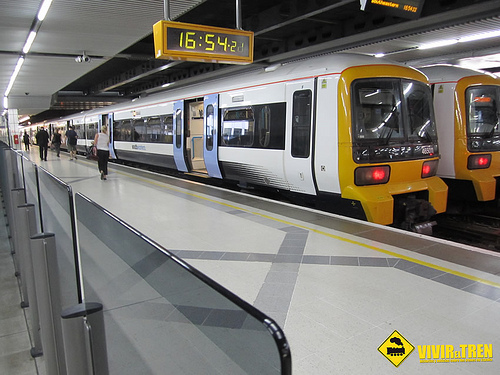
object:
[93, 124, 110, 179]
woman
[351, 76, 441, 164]
window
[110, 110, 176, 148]
window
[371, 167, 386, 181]
red ligth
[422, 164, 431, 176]
red ligth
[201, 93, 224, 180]
door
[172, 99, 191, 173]
door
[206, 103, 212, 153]
window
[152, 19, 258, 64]
sign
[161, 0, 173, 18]
pole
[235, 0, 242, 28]
pole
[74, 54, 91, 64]
camera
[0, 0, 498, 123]
ceiling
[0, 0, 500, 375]
train station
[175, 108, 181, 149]
window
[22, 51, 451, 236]
train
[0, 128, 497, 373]
platform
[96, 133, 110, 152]
shirt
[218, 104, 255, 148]
window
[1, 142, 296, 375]
glass panels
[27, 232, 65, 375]
poles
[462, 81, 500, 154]
window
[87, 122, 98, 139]
window